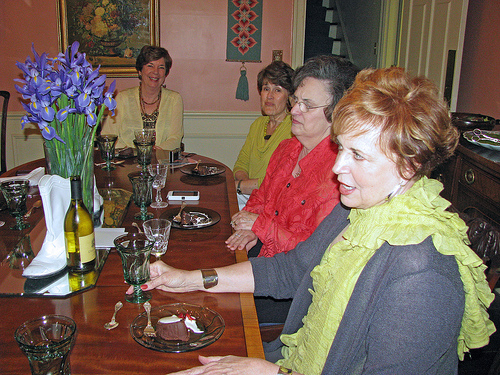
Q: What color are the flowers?
A: Purple.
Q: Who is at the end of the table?
A: A woman.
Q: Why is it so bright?
A: Lights are on.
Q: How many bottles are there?
A: One.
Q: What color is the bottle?
A: Green.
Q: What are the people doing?
A: Sitting.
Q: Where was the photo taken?
A: Dining room.